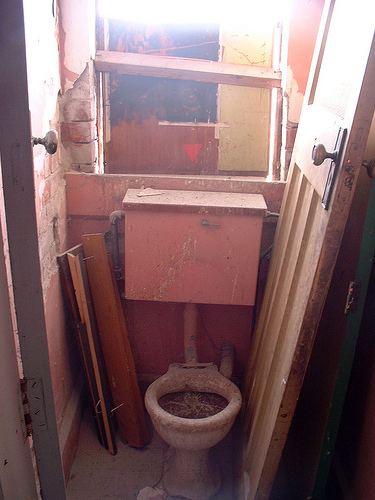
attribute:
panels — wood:
[46, 221, 168, 464]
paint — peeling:
[67, 166, 114, 217]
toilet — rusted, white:
[137, 356, 248, 499]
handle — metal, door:
[313, 133, 344, 189]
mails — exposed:
[91, 398, 123, 419]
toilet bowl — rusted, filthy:
[146, 363, 241, 498]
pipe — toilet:
[182, 303, 199, 364]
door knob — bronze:
[310, 141, 338, 165]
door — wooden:
[235, 0, 374, 499]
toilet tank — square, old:
[117, 187, 269, 307]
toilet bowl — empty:
[140, 357, 245, 495]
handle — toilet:
[186, 210, 236, 240]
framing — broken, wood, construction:
[95, 49, 281, 89]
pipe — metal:
[106, 203, 127, 286]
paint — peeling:
[40, 42, 87, 121]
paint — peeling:
[45, 12, 94, 124]